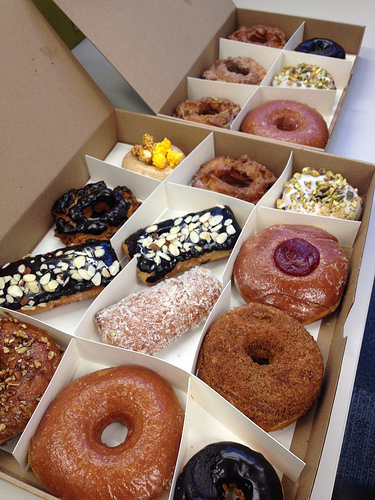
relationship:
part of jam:
[297, 248, 307, 262] [273, 235, 320, 277]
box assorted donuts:
[84, 5, 364, 145] [0, 237, 122, 319]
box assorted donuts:
[11, 67, 331, 498] [172, 22, 339, 139]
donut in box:
[228, 15, 285, 48] [3, 103, 373, 497]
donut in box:
[293, 32, 346, 60] [3, 103, 373, 497]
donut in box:
[199, 54, 269, 86] [3, 103, 373, 497]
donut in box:
[268, 56, 336, 94] [3, 103, 373, 497]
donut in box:
[173, 91, 240, 129] [3, 103, 373, 497]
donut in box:
[237, 99, 327, 152] [3, 103, 373, 497]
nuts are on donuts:
[27, 247, 121, 293] [0, 237, 122, 319]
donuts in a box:
[0, 237, 122, 319] [62, 87, 363, 372]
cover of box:
[0, 0, 114, 243] [1, 0, 373, 499]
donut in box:
[197, 155, 272, 201] [82, 108, 358, 399]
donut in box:
[237, 99, 330, 151] [54, 0, 365, 150]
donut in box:
[233, 223, 350, 325] [1, 0, 373, 499]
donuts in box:
[0, 237, 122, 319] [1, 0, 373, 499]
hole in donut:
[94, 412, 130, 446] [239, 98, 328, 148]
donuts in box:
[64, 206, 329, 376] [1, 0, 373, 499]